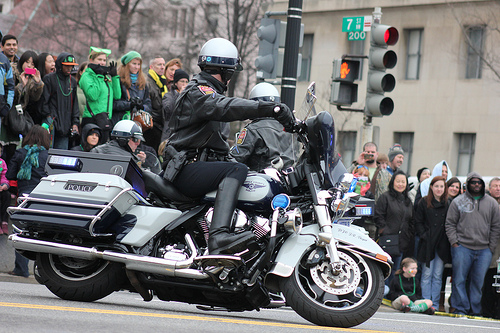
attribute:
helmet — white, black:
[195, 39, 239, 70]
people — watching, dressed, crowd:
[8, 57, 177, 181]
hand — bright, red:
[340, 58, 350, 80]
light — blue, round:
[269, 190, 295, 209]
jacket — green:
[80, 72, 123, 121]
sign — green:
[335, 16, 366, 36]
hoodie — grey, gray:
[452, 192, 500, 238]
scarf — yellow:
[144, 68, 169, 95]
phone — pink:
[22, 69, 38, 78]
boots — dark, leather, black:
[214, 176, 256, 253]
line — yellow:
[12, 300, 279, 325]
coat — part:
[415, 200, 453, 263]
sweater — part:
[390, 278, 434, 296]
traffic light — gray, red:
[370, 20, 392, 129]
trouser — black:
[179, 158, 253, 195]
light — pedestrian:
[321, 58, 367, 89]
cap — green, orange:
[53, 56, 75, 68]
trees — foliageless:
[59, 7, 253, 58]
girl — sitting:
[387, 243, 440, 321]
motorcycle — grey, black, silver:
[8, 37, 388, 327]